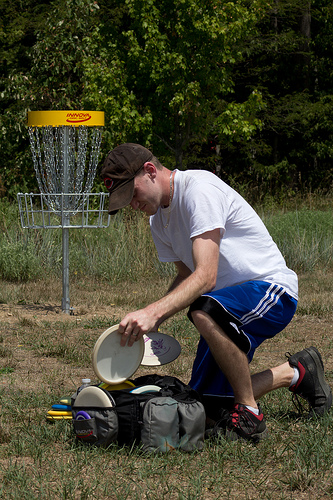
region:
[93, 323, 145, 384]
white frisbee in man's hand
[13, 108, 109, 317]
metal pole with metal device on top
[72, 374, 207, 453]
black and gray back with frisbees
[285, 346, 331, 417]
black with red tennis shoe on man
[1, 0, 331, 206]
tall bushy green trees in background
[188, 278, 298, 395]
blue shorts on man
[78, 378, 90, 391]
water bottle poking out of bag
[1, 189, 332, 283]
tall patch of grass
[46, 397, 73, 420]
stack of yellow and blue frisbees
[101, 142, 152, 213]
brown hat on man's head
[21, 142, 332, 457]
man has multiple frisbees, possibly skeet targets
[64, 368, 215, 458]
dude's bag is by innova, probably most of his stuff too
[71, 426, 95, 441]
innova logo on bag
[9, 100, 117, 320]
thing in back is "sport disc catcher" --frisbee catcher, essentially-- for practice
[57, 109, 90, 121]
innova made it too, cf 'innova' logo up top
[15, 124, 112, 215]
metal chains of 'sport disc catcher'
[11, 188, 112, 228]
metal basket of 'sport disc catcher'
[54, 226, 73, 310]
metal pole holding metal array of 'sport disc catcher' upright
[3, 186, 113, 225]
basket, just so you know, is portable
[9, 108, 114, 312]
whole metal business of 'sport disc catcher' has galvanized finish-- except for top, which is eye catching yellow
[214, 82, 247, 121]
Green leaf on a tree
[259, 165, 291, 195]
Green leaf on a tree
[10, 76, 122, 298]
Yellow and silver net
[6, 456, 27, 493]
Patch of green grass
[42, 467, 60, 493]
Patch of green grass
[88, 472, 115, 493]
Patch of green grass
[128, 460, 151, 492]
Patch of green grass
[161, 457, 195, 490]
Patch of green grass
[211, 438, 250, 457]
Patch of green grass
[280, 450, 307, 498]
Patch of green grass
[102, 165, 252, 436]
he is on one knee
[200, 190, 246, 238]
the shirt is white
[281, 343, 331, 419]
the shoes are black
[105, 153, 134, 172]
the hat is brown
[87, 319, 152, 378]
the frisbee is white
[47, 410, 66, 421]
the frisbee is yellow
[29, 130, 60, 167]
the chain is silver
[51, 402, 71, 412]
the frisbee is blue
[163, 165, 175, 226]
he is wearing a necklace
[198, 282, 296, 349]
man kneeling in blue shorts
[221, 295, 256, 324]
shorts are blue and white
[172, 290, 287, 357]
shorts are blue with black trim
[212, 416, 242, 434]
man wearing black and red shoes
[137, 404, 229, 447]
gray outside pouch of bag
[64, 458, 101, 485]
grass is brown and green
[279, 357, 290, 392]
man wears short white socks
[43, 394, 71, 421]
plates are yellow and blue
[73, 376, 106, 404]
bottle of water in bag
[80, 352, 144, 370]
man holding white plate